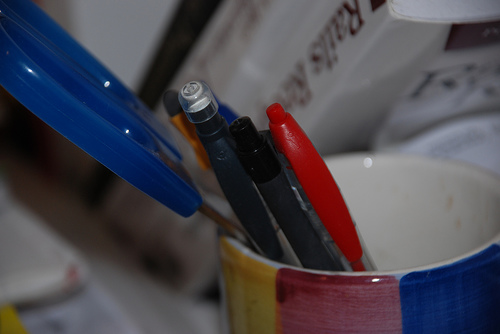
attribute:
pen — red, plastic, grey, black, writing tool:
[265, 101, 376, 272]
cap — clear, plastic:
[177, 80, 219, 124]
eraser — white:
[181, 81, 203, 103]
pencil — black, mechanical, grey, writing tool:
[178, 80, 306, 270]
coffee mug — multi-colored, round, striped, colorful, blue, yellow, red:
[216, 150, 500, 334]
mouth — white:
[231, 156, 499, 273]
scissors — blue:
[1, 0, 268, 259]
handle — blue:
[1, 1, 203, 218]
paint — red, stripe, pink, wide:
[275, 267, 402, 334]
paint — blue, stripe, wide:
[399, 243, 499, 333]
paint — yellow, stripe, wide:
[217, 232, 278, 334]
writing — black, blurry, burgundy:
[272, 1, 364, 112]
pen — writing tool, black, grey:
[226, 115, 351, 273]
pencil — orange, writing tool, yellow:
[161, 89, 215, 173]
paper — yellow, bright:
[1, 302, 27, 334]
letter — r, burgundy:
[342, 1, 365, 36]